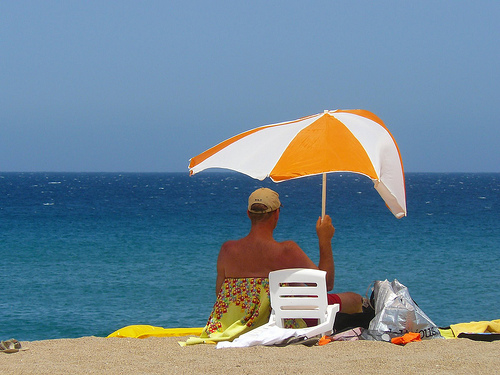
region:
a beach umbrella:
[172, 94, 467, 266]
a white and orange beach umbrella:
[146, 76, 457, 248]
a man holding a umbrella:
[146, 59, 428, 366]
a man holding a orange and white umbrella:
[166, 97, 423, 331]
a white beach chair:
[244, 250, 391, 356]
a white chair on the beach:
[228, 230, 355, 340]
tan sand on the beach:
[4, 314, 489, 373]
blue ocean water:
[8, 150, 497, 325]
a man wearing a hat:
[213, 165, 357, 282]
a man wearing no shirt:
[195, 146, 425, 311]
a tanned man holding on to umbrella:
[180, 110, 426, 372]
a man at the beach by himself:
[113, 217, 488, 367]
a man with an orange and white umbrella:
[160, 86, 499, 368]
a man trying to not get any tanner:
[20, 25, 497, 374]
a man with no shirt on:
[59, 87, 498, 373]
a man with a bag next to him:
[293, 197, 498, 369]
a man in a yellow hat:
[100, 53, 459, 373]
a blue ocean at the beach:
[23, 95, 286, 373]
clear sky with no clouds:
[23, 0, 478, 260]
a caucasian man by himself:
[128, 79, 414, 374]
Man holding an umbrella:
[172, 91, 429, 341]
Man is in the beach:
[197, 177, 385, 339]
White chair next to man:
[232, 264, 353, 352]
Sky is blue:
[2, 5, 497, 153]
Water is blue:
[8, 172, 498, 323]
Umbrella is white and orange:
[175, 97, 425, 224]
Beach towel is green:
[175, 271, 309, 343]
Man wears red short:
[200, 181, 380, 333]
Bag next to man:
[358, 270, 448, 352]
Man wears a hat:
[204, 180, 374, 335]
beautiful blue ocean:
[1, 156, 160, 285]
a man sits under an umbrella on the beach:
[172, 93, 437, 355]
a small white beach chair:
[240, 260, 361, 363]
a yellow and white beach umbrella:
[176, 80, 416, 242]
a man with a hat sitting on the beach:
[210, 185, 382, 364]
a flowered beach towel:
[182, 268, 271, 348]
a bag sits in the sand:
[354, 261, 454, 363]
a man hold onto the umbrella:
[212, 145, 347, 293]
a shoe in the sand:
[2, 321, 43, 361]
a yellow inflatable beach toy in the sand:
[86, 295, 217, 353]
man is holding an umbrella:
[141, 82, 401, 357]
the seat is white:
[253, 260, 376, 361]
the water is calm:
[23, 200, 161, 307]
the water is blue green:
[41, 180, 254, 363]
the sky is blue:
[64, 60, 161, 175]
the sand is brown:
[64, 333, 134, 367]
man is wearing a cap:
[219, 176, 299, 225]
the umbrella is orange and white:
[198, 69, 480, 276]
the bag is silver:
[360, 265, 495, 372]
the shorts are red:
[274, 263, 364, 336]